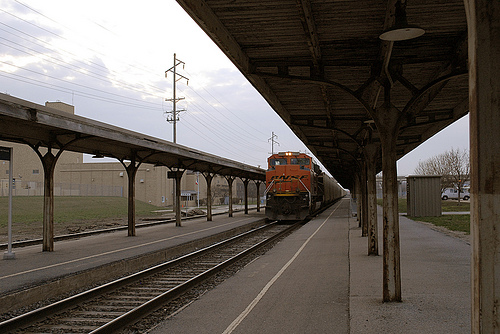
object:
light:
[282, 149, 297, 159]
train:
[242, 138, 327, 237]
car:
[438, 185, 473, 201]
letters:
[262, 172, 310, 182]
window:
[272, 152, 307, 167]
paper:
[276, 158, 286, 171]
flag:
[0, 144, 11, 162]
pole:
[0, 149, 15, 257]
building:
[90, 169, 173, 202]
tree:
[427, 152, 467, 175]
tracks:
[12, 204, 288, 334]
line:
[52, 47, 148, 107]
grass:
[84, 198, 112, 210]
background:
[412, 153, 457, 234]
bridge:
[233, 6, 499, 192]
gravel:
[239, 203, 262, 229]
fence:
[181, 166, 202, 202]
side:
[63, 122, 203, 268]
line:
[73, 221, 152, 282]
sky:
[115, 114, 159, 124]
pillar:
[380, 133, 403, 303]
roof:
[66, 106, 147, 165]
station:
[48, 124, 274, 274]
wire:
[20, 24, 176, 124]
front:
[272, 168, 305, 202]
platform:
[102, 195, 225, 312]